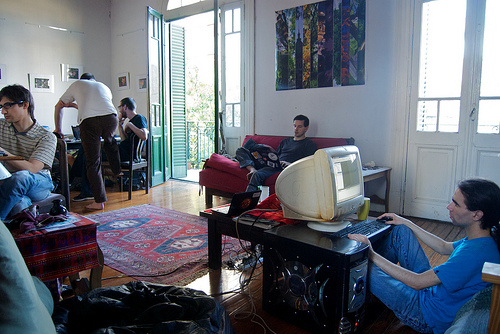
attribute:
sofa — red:
[199, 132, 366, 212]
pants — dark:
[76, 117, 120, 205]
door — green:
[144, 5, 166, 185]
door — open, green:
[170, 28, 198, 180]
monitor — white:
[273, 143, 367, 223]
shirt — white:
[59, 72, 126, 132]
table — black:
[204, 187, 396, 325]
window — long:
[473, 0, 499, 134]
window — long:
[415, 0, 467, 132]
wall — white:
[248, 69, 284, 126]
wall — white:
[54, 33, 122, 69]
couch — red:
[203, 140, 338, 201]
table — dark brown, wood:
[212, 200, 392, 317]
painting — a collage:
[269, 2, 370, 92]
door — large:
[141, 4, 174, 191]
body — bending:
[59, 81, 139, 191]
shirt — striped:
[2, 118, 62, 175]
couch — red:
[193, 125, 382, 221]